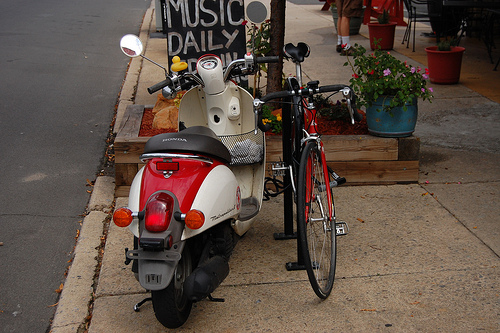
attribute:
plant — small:
[340, 50, 431, 105]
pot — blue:
[366, 98, 414, 133]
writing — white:
[162, 3, 244, 53]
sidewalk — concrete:
[351, 182, 487, 315]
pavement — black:
[18, 170, 95, 230]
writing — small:
[153, 133, 195, 142]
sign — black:
[147, 2, 253, 92]